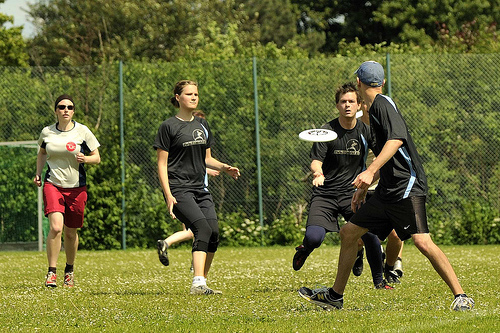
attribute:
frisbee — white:
[294, 115, 342, 147]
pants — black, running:
[162, 186, 222, 256]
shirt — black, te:
[151, 112, 219, 195]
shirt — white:
[35, 123, 100, 193]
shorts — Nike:
[373, 203, 433, 235]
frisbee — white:
[293, 123, 340, 146]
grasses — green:
[101, 288, 311, 331]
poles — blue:
[112, 52, 132, 250]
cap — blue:
[350, 54, 390, 94]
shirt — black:
[152, 112, 215, 184]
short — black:
[179, 192, 217, 241]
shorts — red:
[41, 177, 93, 218]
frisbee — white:
[295, 119, 338, 149]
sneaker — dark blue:
[293, 279, 343, 317]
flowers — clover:
[92, 264, 141, 278]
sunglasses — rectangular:
[55, 97, 76, 113]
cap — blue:
[352, 55, 392, 89]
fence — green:
[1, 61, 499, 248]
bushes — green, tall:
[4, 5, 498, 247]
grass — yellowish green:
[4, 249, 494, 332]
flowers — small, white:
[2, 254, 498, 324]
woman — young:
[32, 100, 112, 285]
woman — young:
[153, 80, 249, 301]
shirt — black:
[157, 120, 218, 185]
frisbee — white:
[297, 129, 338, 149]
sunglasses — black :
[48, 99, 75, 109]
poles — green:
[113, 57, 284, 239]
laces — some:
[296, 275, 482, 318]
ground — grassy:
[4, 250, 392, 330]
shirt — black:
[365, 95, 421, 193]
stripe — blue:
[388, 137, 415, 171]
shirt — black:
[160, 118, 211, 191]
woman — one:
[154, 76, 222, 291]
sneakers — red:
[35, 259, 83, 286]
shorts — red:
[29, 175, 90, 218]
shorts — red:
[40, 183, 88, 221]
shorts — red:
[38, 178, 92, 223]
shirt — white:
[35, 120, 95, 190]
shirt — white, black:
[42, 126, 97, 196]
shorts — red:
[32, 177, 94, 216]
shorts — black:
[166, 171, 220, 206]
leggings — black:
[168, 169, 228, 261]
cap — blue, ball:
[353, 51, 391, 91]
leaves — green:
[97, 5, 310, 152]